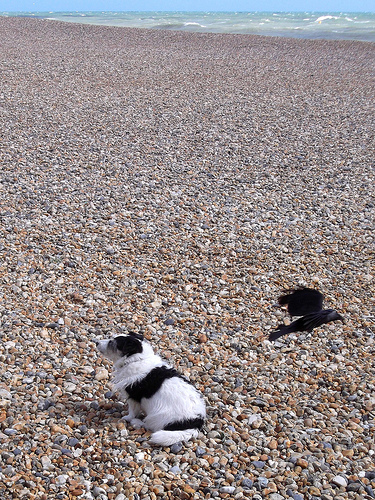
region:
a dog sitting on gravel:
[94, 321, 211, 452]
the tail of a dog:
[149, 426, 203, 447]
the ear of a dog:
[120, 332, 145, 355]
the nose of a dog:
[91, 336, 102, 346]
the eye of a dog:
[104, 336, 116, 350]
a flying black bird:
[258, 283, 352, 348]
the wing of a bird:
[279, 284, 326, 317]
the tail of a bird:
[265, 321, 288, 345]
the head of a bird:
[323, 303, 348, 324]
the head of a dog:
[92, 329, 152, 361]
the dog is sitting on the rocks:
[95, 330, 205, 444]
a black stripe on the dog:
[126, 367, 186, 400]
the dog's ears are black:
[115, 329, 148, 354]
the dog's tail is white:
[151, 428, 198, 446]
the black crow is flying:
[267, 286, 345, 341]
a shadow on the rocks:
[46, 397, 123, 427]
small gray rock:
[253, 459, 265, 468]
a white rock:
[332, 475, 349, 487]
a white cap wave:
[312, 15, 352, 23]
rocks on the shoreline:
[0, 16, 373, 497]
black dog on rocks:
[97, 322, 211, 447]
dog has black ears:
[115, 321, 151, 368]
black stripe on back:
[109, 366, 170, 403]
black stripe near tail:
[143, 414, 209, 454]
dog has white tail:
[159, 426, 192, 450]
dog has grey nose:
[70, 339, 119, 349]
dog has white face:
[88, 325, 127, 366]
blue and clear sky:
[171, 0, 289, 18]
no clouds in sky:
[143, 2, 335, 8]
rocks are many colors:
[110, 41, 328, 222]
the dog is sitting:
[124, 398, 227, 456]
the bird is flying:
[270, 274, 340, 340]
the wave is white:
[314, 13, 345, 23]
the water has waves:
[146, 10, 268, 29]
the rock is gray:
[240, 478, 252, 487]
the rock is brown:
[236, 413, 247, 421]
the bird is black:
[283, 285, 330, 328]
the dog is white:
[166, 387, 187, 408]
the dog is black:
[139, 378, 158, 391]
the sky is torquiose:
[217, 2, 245, 10]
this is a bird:
[260, 244, 354, 347]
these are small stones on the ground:
[223, 380, 270, 444]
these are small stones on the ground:
[276, 405, 313, 464]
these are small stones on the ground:
[234, 339, 269, 412]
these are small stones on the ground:
[131, 135, 221, 216]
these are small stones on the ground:
[240, 157, 295, 235]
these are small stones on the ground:
[37, 348, 87, 441]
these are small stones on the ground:
[60, 435, 111, 481]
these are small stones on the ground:
[237, 412, 336, 498]